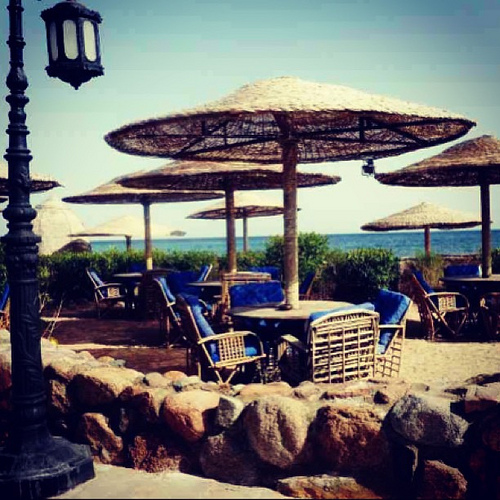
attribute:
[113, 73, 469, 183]
umbrella — big, wooden, straw, brown, white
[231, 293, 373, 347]
table — brown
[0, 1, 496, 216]
sky — big, white, massive, blue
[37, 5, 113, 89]
lamp — hanging, black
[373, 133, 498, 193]
umbrella — hut type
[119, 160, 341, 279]
umbrella — hut type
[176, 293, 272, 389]
chair — wicker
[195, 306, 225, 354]
cushion — blue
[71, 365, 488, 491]
wall — rock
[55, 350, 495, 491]
wall — rock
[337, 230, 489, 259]
ocean — blue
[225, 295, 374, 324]
table — round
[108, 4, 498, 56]
sky — clear, blue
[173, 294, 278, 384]
chairs — brown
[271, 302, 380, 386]
chairs — brown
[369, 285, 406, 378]
chairs — brown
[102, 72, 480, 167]
umbrella — wicker, hut type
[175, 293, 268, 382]
chair — brown, wooden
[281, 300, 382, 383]
chair — brown, wooden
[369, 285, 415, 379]
chair — brown, wooden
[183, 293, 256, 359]
cushion — blue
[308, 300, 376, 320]
cushion — blue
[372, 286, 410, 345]
cushion — blue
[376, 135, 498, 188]
umbrella — wooden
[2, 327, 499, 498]
wall — rock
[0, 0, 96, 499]
post — black, decorative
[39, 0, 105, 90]
lamp — white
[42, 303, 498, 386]
ground — light brown